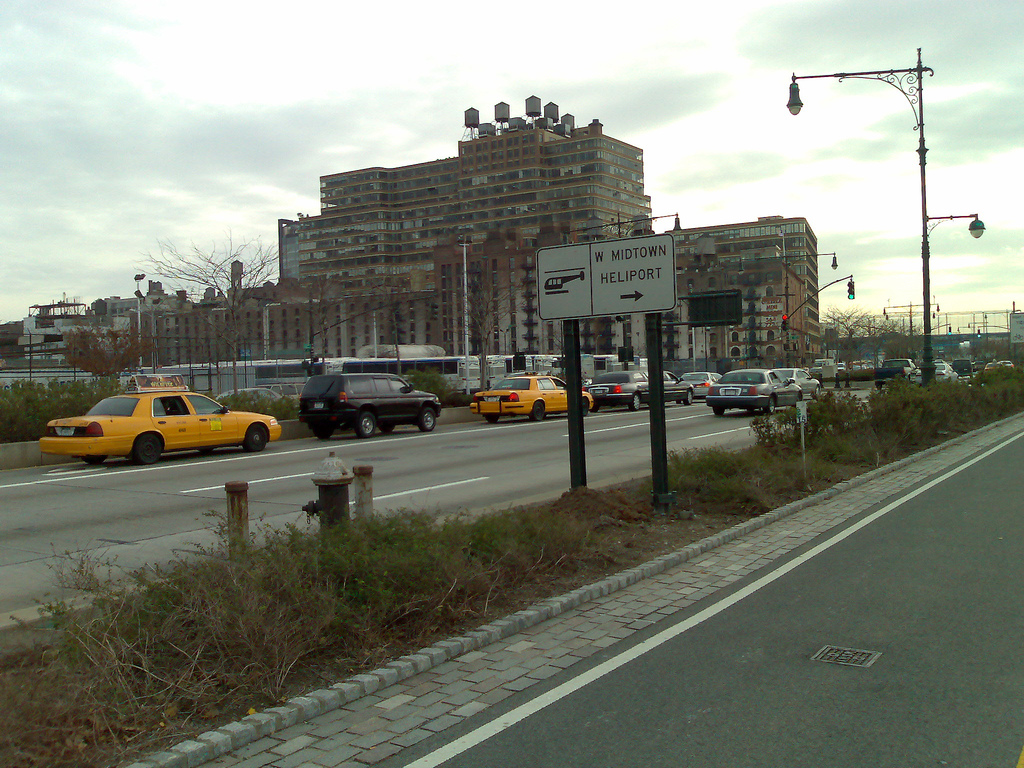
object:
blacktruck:
[298, 373, 441, 442]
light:
[967, 220, 984, 238]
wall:
[320, 167, 381, 213]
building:
[132, 96, 824, 380]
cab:
[39, 372, 283, 465]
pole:
[915, 48, 932, 376]